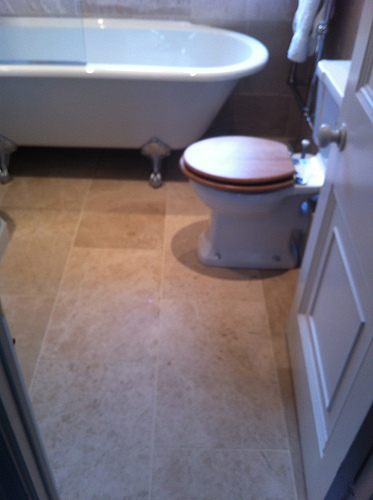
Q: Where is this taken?
A: In a bathroom.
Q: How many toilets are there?
A: One.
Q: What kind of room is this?
A: Bathroom.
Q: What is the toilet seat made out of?
A: Wood.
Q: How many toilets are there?
A: 1.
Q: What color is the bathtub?
A: White.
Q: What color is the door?
A: White.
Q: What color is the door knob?
A: Silver.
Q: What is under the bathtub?
A: Tile floor.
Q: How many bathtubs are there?
A: 1.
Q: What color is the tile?
A: Tan.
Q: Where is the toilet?
A: To the right of the bathroom.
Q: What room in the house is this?
A: Bathroom.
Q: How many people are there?
A: None.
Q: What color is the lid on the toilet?
A: Brown.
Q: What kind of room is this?
A: Bathroom.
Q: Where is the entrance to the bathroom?
A: In front.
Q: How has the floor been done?
A: Tiled.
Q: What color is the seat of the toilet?
A: Brown.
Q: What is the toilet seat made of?
A: Wood.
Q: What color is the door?
A: White.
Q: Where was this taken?
A: In a house.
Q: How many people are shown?
A: None.